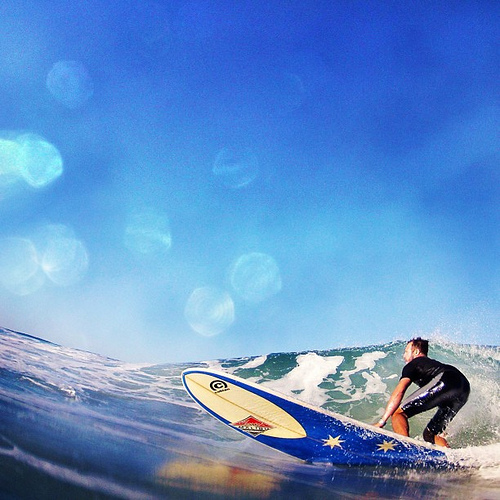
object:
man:
[371, 336, 470, 448]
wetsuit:
[399, 356, 471, 445]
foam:
[257, 349, 400, 416]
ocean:
[0, 324, 500, 500]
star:
[321, 434, 346, 449]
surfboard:
[180, 366, 450, 467]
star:
[375, 439, 400, 453]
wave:
[122, 339, 500, 479]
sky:
[1, 0, 500, 364]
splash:
[409, 313, 488, 346]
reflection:
[0, 449, 454, 500]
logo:
[209, 379, 230, 393]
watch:
[378, 417, 387, 426]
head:
[403, 336, 429, 364]